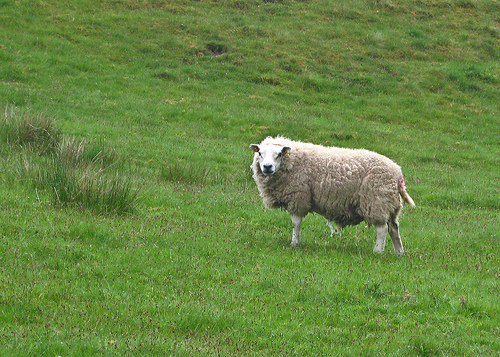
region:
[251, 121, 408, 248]
this is a ram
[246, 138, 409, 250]
the ram is standing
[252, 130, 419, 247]
the ram is wooly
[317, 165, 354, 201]
the wool is grey in coor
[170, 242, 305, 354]
the grass are green in color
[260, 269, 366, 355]
the grass are short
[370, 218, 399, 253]
these are the rear legs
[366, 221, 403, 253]
the legs are short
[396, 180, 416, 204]
the tail is short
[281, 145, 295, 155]
this is the ear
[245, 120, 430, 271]
a white sheep in grass field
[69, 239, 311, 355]
green grass on the ground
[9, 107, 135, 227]
tall patch of green grass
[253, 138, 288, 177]
head of the white sheep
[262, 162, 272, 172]
nose of the white sheep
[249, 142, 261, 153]
right ear of white sheep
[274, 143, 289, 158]
left ear of white sheep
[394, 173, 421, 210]
tail of white sheep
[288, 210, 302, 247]
front left leg of white sheep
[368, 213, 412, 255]
back legs of white sheep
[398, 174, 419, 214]
Tail in the back of sheep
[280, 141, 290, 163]
right ear on sheeps head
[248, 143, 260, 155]
left ear on sheeps head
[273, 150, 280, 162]
right eye on sheeps face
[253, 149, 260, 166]
left eye on sheeps face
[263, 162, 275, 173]
Nose on sheeps face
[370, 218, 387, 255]
back rght foot on sheep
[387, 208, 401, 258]
right foot on sheep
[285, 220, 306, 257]
front left foot on sheep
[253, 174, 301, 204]
wool under sheeps face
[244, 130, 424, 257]
a sheep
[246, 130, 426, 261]
an animal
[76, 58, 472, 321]
a sheep in a field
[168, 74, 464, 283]
an animal in a field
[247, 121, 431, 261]
the sheep looks directly at the camera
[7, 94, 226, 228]
some grass is longer than the rest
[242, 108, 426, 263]
the sheep has not been shaved yet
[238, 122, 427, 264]
the animal is alone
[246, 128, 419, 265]
the sheep is alone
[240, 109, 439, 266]
the sheep is standing in the grass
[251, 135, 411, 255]
white sheep standing in a field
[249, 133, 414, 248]
sheep covered in wool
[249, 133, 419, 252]
sheep standing in the green grass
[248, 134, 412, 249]
sheep looking at the camera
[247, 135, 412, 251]
sheep walking through an open field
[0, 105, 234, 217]
weeds growing in the open field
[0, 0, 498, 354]
open field with green grass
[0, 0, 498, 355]
open field with a sheep in the middle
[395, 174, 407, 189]
pink spot on the sheep's tail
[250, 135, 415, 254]
sheep about to feed on grass